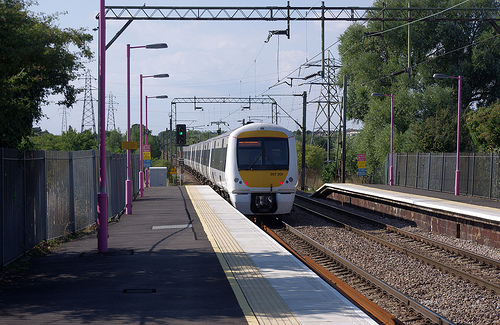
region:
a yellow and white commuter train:
[176, 119, 306, 218]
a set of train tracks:
[243, 209, 450, 324]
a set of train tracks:
[280, 183, 496, 296]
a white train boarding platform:
[183, 176, 369, 323]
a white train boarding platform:
[325, 179, 499, 228]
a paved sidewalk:
[15, 161, 226, 323]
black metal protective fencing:
[380, 147, 499, 199]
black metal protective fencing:
[3, 143, 143, 248]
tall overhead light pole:
[120, 34, 167, 209]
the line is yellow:
[228, 273, 239, 299]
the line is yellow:
[221, 276, 233, 302]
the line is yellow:
[234, 287, 244, 309]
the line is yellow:
[231, 280, 241, 302]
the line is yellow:
[231, 279, 244, 314]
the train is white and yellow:
[183, 126, 317, 214]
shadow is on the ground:
[96, 243, 260, 321]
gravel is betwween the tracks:
[332, 233, 455, 318]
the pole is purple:
[448, 131, 460, 198]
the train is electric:
[184, 138, 304, 222]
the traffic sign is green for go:
[172, 126, 203, 146]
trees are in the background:
[412, 121, 495, 143]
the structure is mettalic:
[308, 90, 340, 150]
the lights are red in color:
[236, 175, 257, 192]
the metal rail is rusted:
[344, 261, 377, 308]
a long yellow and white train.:
[173, 114, 310, 204]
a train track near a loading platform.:
[264, 222, 498, 324]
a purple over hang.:
[89, 0, 498, 252]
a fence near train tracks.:
[0, 154, 161, 277]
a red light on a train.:
[273, 177, 286, 190]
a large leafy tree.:
[349, 86, 474, 188]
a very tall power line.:
[96, 86, 131, 133]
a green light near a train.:
[169, 114, 197, 186]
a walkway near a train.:
[30, 187, 244, 324]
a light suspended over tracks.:
[144, 34, 169, 56]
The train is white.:
[168, 109, 315, 217]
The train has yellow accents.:
[205, 98, 322, 224]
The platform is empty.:
[136, 177, 218, 317]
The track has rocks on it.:
[300, 210, 427, 322]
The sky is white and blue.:
[161, 22, 258, 77]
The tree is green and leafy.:
[336, 22, 496, 154]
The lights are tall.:
[107, 19, 198, 211]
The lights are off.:
[78, 1, 167, 248]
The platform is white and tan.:
[172, 174, 271, 324]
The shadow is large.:
[36, 158, 208, 324]